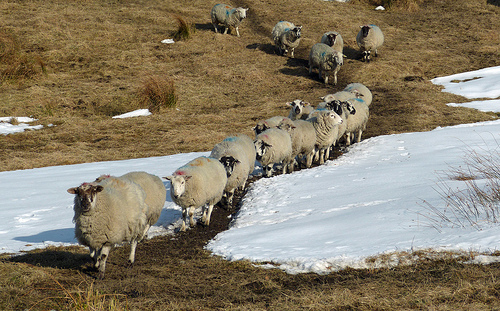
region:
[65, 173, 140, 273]
fluffy white colored sheep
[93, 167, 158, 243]
fluffy white colored sheep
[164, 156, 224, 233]
fluffy white colored sheep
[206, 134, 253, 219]
fluffy white colored sheep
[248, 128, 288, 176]
fluffy white colored sheep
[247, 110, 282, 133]
fluffy white colored sheep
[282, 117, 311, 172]
fluffy white colored sheep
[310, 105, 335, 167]
fluffy white colored sheep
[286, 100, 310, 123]
fluffy white colored sheep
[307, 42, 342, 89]
fluffy white colored sheep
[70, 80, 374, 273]
row of sheep in a field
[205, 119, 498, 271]
patches of snow in field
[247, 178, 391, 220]
footprints in the snow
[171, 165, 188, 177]
red spot on sheep's back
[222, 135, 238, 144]
blue spot on sheep's back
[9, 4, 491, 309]
dead brown grass in field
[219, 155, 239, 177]
black face on sheep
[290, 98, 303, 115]
black circles around eyes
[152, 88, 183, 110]
small bit of green grass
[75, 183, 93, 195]
brown spots on face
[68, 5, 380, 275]
a line of sheep walking up a hill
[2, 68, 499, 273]
snow on the brown grassy hill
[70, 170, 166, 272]
the sheep in the front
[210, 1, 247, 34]
the last sheep in line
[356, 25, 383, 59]
the sheep with the black head that is out of line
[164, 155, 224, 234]
sheep with the white face, second in line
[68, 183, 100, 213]
the front sheep's face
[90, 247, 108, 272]
the lead sheep's front legs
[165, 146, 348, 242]
the path between the snow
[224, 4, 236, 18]
blue and red dots on the last sheep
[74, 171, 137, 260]
white sheep in grass field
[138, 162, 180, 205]
white sheep in grass field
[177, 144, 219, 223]
white sheep in grass field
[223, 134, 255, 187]
white sheep in grass field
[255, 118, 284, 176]
white sheep in grass field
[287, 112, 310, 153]
white sheep in grass field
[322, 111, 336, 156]
white sheep in grass field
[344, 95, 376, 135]
white sheep in grass field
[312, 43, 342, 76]
white sheep in grass field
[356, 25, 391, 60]
white sheep in grass field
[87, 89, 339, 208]
these are some sheep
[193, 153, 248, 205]
the sheep are big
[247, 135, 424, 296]
there is snow on the ground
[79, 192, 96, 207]
this is a head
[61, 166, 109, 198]
the head is large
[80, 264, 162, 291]
these are feet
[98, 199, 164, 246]
there is wool on the sheep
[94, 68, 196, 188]
this is a tuft of grass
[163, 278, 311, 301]
the grass is parched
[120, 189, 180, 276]
the sheep are yellow